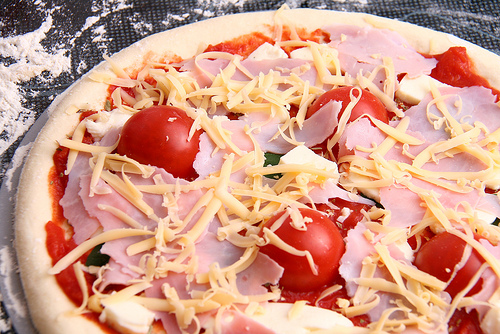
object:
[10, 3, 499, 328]
pizza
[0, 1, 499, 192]
flour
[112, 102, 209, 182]
cherry tomato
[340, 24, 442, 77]
ham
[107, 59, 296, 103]
cheese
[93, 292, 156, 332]
cheese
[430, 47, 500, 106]
tomato sauce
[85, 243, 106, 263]
onion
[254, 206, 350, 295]
tomato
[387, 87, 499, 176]
ham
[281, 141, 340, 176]
cheese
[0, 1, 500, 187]
table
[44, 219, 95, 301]
sauce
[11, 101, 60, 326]
dough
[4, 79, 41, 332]
tray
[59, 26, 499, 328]
toppings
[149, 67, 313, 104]
strips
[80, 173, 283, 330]
ham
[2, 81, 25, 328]
sheet